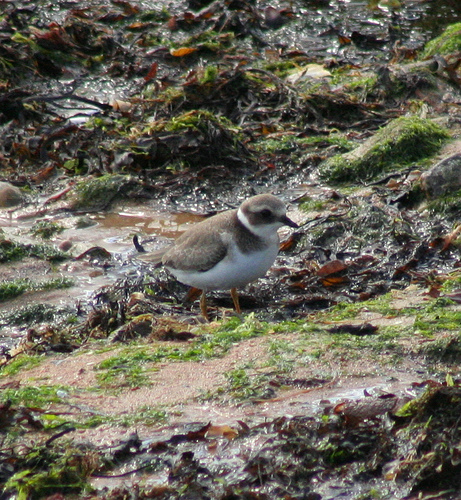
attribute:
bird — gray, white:
[131, 190, 299, 326]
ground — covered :
[1, 0, 460, 497]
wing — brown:
[126, 227, 229, 273]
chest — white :
[213, 228, 295, 289]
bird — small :
[106, 179, 335, 325]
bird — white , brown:
[119, 179, 343, 329]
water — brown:
[103, 204, 195, 252]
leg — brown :
[196, 290, 213, 323]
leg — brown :
[225, 286, 244, 314]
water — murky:
[57, 186, 240, 250]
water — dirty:
[106, 208, 173, 240]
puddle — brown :
[82, 186, 190, 262]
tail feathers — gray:
[125, 237, 165, 272]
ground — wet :
[159, 346, 329, 406]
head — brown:
[246, 194, 284, 229]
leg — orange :
[194, 291, 210, 326]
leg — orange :
[227, 293, 245, 319]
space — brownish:
[164, 342, 241, 388]